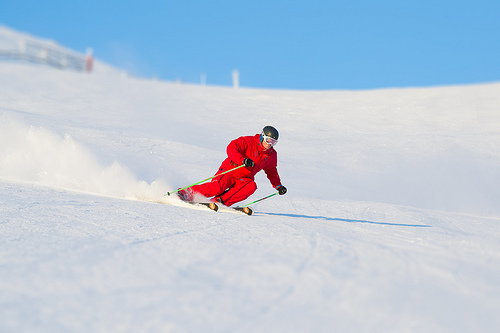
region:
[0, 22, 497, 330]
A skiier on a ski slope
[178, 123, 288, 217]
Skiier is wearing a red snowsuit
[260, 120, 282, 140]
The helmet is black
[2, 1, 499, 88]
The sky is blue and clear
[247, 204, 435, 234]
Skiier's shadow on the snow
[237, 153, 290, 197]
A pair of black gloves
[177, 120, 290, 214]
Skiier is holding two ski poles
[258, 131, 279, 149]
A pair of goggles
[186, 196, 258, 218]
Two black and yellow skis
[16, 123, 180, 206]
Snow flying behind the skiier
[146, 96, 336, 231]
this guy is skiing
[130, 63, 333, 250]
he is skiing on a mountain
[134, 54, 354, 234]
he is skiing down a slope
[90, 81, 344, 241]
he is quickly skiing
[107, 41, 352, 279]
he is on a pair of skis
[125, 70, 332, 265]
he is wearing a red jacket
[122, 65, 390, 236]
he is wearing red pants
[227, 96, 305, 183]
his helmet is black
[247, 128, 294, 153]
his goggles are white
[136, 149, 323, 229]
his ski poles are neon green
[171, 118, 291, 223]
a skier wearing red clothes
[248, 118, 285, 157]
the helmet is color black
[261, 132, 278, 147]
man has goggles on face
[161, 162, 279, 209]
poles are color green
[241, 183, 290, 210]
snow pole on left hand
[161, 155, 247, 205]
snow pole on right hand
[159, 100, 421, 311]
skier is going down the hill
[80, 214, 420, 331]
marks of skis on hill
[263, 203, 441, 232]
shadow cast on the snow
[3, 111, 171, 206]
snow above the ground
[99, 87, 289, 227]
a man skiing down a ski slope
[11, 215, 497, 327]
a thick coat of snow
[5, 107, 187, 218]
the wake of snow behind a snow skier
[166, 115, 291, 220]
a skier wearing an orange ski jumpsuit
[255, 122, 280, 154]
a skier wearing a black helmet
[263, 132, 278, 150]
a skier wearing goggles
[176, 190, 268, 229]
the two skis of a skier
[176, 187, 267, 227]
skis digging through the snow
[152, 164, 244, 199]
a silver ski pole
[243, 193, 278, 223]
a silver ski pole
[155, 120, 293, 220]
A person skiing down a slope